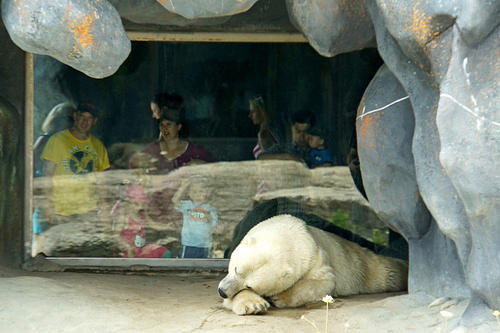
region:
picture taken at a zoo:
[22, 33, 462, 294]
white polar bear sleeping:
[214, 222, 394, 312]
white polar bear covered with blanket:
[216, 181, 408, 317]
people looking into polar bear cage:
[55, 96, 334, 249]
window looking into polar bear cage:
[19, 27, 395, 252]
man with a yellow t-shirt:
[44, 123, 104, 201]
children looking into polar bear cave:
[112, 176, 229, 251]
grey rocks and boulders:
[354, 19, 486, 304]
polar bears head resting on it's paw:
[220, 208, 305, 317]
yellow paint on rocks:
[57, 15, 105, 56]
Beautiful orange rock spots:
[66, 15, 106, 45]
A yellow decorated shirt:
[41, 135, 107, 167]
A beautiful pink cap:
[124, 180, 152, 208]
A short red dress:
[117, 223, 167, 263]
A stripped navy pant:
[171, 245, 216, 260]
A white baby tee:
[178, 199, 219, 247]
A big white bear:
[186, 207, 404, 325]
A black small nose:
[216, 287, 229, 302]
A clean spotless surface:
[23, 284, 185, 326]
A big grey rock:
[439, 75, 497, 314]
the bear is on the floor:
[209, 213, 404, 310]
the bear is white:
[210, 218, 361, 308]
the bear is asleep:
[195, 209, 382, 301]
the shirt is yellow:
[40, 123, 108, 208]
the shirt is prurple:
[128, 139, 222, 171]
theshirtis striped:
[243, 141, 276, 153]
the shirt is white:
[175, 197, 227, 244]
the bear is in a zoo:
[203, 212, 402, 307]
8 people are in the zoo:
[40, 95, 312, 232]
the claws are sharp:
[240, 298, 289, 317]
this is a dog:
[204, 213, 439, 330]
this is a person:
[35, 108, 117, 225]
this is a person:
[127, 103, 207, 182]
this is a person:
[223, 88, 291, 163]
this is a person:
[285, 105, 317, 159]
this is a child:
[303, 118, 330, 164]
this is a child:
[179, 168, 236, 260]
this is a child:
[114, 155, 173, 266]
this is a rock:
[5, 3, 141, 82]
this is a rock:
[342, 70, 430, 241]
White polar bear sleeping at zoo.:
[217, 212, 407, 313]